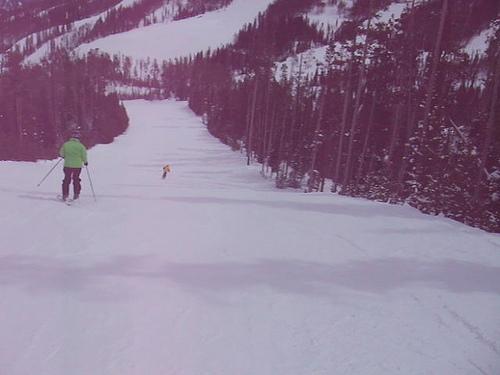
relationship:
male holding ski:
[58, 130, 88, 202] [57, 194, 81, 211]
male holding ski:
[58, 130, 88, 202] [67, 194, 79, 202]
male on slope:
[58, 130, 88, 202] [102, 164, 289, 280]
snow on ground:
[185, 201, 349, 292] [172, 194, 294, 278]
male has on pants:
[58, 130, 88, 202] [59, 162, 86, 197]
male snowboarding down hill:
[35, 125, 100, 205] [21, 199, 390, 368]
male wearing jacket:
[58, 130, 88, 202] [56, 137, 92, 174]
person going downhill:
[161, 164, 170, 180] [125, 96, 198, 157]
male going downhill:
[58, 130, 88, 202] [0, 89, 402, 281]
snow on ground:
[23, 213, 160, 345] [4, 160, 443, 264]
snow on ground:
[388, 268, 478, 361] [6, 160, 497, 372]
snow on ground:
[179, 173, 291, 290] [204, 148, 281, 290]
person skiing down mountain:
[161, 164, 170, 180] [92, 150, 453, 373]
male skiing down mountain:
[58, 130, 88, 202] [92, 150, 453, 373]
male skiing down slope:
[58, 130, 88, 202] [95, 155, 447, 373]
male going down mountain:
[58, 130, 88, 202] [104, 9, 292, 146]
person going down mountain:
[161, 164, 170, 180] [104, 9, 292, 146]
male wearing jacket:
[58, 130, 88, 202] [60, 134, 87, 169]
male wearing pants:
[58, 130, 88, 202] [56, 166, 86, 196]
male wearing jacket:
[58, 130, 88, 202] [59, 140, 93, 168]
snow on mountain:
[0, 0, 498, 373] [0, 3, 498, 373]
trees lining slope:
[1, 0, 499, 233] [164, 4, 499, 205]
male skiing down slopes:
[58, 130, 88, 202] [105, 100, 387, 357]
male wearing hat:
[58, 130, 88, 202] [69, 128, 83, 139]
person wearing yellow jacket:
[161, 164, 170, 180] [161, 167, 176, 175]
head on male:
[68, 126, 81, 146] [58, 130, 88, 202]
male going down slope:
[58, 130, 88, 202] [1, 97, 498, 373]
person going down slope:
[161, 164, 170, 180] [1, 97, 498, 373]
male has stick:
[58, 130, 88, 202] [85, 165, 99, 200]